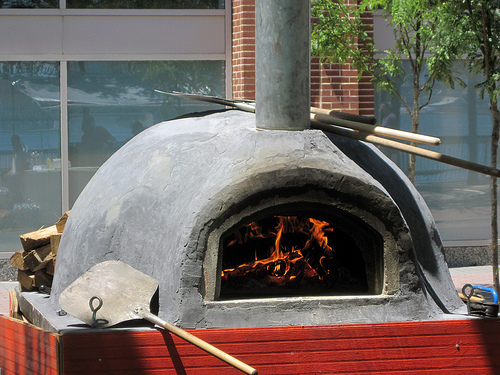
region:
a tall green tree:
[310, 0, 497, 186]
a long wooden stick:
[149, 84, 499, 183]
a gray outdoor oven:
[24, 107, 484, 327]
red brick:
[1, 315, 60, 373]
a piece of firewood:
[16, 212, 56, 251]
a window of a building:
[70, 62, 227, 202]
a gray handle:
[256, 0, 313, 132]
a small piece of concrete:
[445, 244, 495, 266]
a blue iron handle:
[458, 281, 496, 301]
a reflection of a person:
[76, 112, 123, 152]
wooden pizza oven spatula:
[55, 255, 257, 374]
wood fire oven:
[167, 151, 400, 311]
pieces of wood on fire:
[245, 223, 342, 289]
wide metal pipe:
[248, 1, 313, 131]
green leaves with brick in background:
[315, 6, 377, 106]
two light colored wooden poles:
[320, 112, 499, 175]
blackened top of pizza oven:
[220, 164, 382, 204]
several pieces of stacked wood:
[16, 208, 52, 292]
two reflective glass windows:
[6, 11, 211, 262]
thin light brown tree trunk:
[405, 54, 427, 179]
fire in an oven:
[238, 196, 365, 285]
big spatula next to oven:
[52, 241, 196, 342]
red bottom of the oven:
[311, 312, 377, 368]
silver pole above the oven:
[218, 10, 319, 150]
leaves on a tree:
[363, 14, 453, 74]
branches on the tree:
[398, 76, 448, 124]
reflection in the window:
[2, 96, 61, 181]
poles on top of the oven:
[353, 96, 437, 186]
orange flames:
[229, 214, 336, 284]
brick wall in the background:
[325, 66, 362, 104]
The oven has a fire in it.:
[140, 120, 445, 325]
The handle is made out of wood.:
[145, 310, 263, 373]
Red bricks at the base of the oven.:
[290, 330, 480, 365]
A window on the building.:
[6, 85, 51, 200]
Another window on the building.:
[75, 70, 220, 110]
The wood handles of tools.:
[310, 100, 495, 180]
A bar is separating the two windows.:
[47, 65, 78, 208]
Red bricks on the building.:
[323, 66, 369, 108]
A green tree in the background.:
[330, 5, 496, 111]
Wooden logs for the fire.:
[0, 207, 72, 292]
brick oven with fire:
[136, 131, 416, 333]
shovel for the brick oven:
[35, 240, 250, 356]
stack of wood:
[4, 203, 103, 287]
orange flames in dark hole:
[254, 228, 337, 276]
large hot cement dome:
[35, 50, 445, 356]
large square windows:
[9, 48, 232, 274]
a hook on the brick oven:
[74, 286, 112, 339]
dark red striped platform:
[24, 310, 464, 368]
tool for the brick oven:
[146, 25, 485, 202]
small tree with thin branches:
[331, 16, 484, 219]